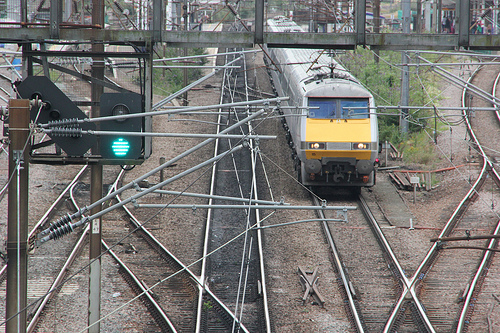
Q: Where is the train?
A: On train tracks.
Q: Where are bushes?
A: Next to the train.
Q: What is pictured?
A: Train.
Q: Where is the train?
A: On tracks.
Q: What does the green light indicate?
A: The train can go.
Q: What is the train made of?
A: Metal.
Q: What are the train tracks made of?
A: Metal.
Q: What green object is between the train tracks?
A: Grass.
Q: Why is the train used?
A: For transport.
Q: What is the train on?
A: Tracks.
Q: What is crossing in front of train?
A: Tracks.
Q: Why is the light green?
A: Signals go.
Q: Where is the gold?
A: Front of train.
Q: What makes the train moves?
A: Electricity.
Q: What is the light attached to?
A: Poles.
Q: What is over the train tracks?
A: Metal crate.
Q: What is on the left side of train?
A: Grass.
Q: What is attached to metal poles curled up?
A: Cables.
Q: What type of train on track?
A: Passenger.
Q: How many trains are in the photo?
A: One.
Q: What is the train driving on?
A: A train track.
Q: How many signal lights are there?
A: One.